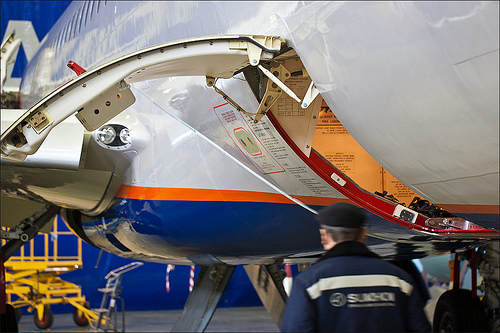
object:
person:
[245, 178, 465, 331]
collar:
[316, 240, 379, 260]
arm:
[278, 282, 319, 331]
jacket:
[276, 251, 428, 332]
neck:
[324, 237, 367, 253]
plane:
[3, 2, 499, 333]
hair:
[320, 224, 362, 243]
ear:
[358, 226, 368, 244]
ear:
[319, 228, 329, 244]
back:
[329, 289, 397, 313]